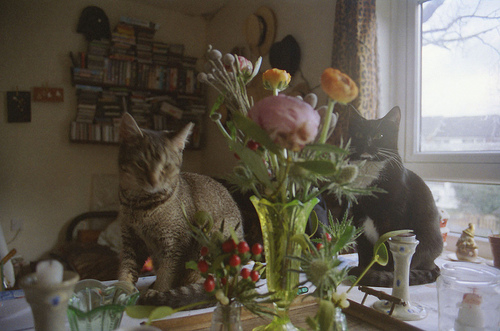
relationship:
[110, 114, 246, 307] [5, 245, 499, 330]
cat on table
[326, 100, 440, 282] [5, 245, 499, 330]
cat on table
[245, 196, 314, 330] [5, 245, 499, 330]
vase on table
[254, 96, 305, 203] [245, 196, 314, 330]
flower in vase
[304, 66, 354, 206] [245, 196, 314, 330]
flower in vase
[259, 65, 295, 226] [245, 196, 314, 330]
flower in vase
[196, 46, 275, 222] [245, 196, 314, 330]
flower in vase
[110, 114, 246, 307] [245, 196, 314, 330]
cat sees vase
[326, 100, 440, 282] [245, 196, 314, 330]
cat sees vase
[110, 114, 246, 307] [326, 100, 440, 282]
cat with cat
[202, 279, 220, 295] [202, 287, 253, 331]
berry in vase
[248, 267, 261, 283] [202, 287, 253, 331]
berry in vase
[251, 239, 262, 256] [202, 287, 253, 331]
berry in vase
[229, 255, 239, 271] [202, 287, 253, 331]
berry in vase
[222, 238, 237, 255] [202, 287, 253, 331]
berry in vase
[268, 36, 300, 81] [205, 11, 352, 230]
hat on wall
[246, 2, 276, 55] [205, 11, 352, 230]
hat on wall